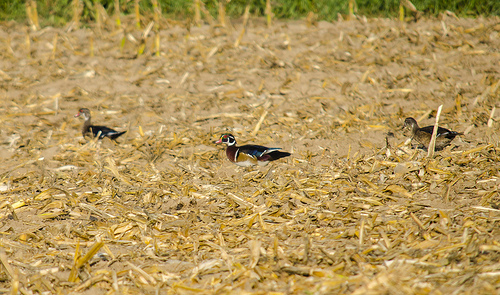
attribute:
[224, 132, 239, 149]
stripes —  white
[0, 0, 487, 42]
grass —  tall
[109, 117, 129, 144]
tail —  black,  upturned,  duck's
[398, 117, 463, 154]
bird —  three,  group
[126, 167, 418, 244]
wood chips —  wood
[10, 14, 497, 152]
mulch — brown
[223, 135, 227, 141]
redeye — red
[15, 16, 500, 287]
ground —  brown,  dirt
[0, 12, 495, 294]
chips —  wood ,  ground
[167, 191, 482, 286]
straw — yellow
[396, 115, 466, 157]
bird —  black and brown 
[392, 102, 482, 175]
birds —  three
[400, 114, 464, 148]
bird —  three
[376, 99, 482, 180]
tan straw —  tan ,  blade,  upright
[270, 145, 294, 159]
tail —  dark brown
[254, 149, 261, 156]
section —   green 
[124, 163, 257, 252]
straw — yellow